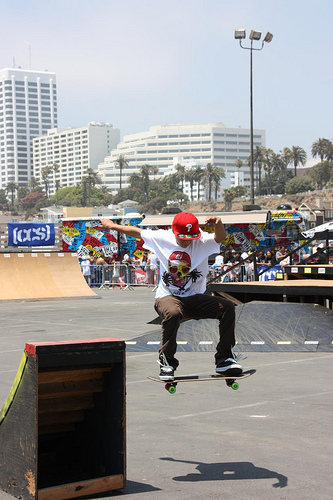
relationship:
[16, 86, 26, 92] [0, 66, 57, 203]
window of a building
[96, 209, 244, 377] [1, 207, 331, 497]
man in a park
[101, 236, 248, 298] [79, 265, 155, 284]
spectators standing near fence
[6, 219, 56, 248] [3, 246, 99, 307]
sign hung near ramp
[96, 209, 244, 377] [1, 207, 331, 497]
man in park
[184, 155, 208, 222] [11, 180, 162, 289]
palm trees in distance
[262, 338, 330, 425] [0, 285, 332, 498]
part of a surface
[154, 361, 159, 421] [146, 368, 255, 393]
part of a board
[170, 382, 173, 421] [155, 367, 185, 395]
part of a wheel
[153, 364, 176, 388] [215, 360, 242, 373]
part of a shoe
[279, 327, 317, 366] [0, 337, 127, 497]
part of a ramp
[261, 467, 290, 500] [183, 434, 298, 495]
part of a shadow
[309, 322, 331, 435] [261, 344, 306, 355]
edge of a court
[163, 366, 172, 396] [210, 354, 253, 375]
tip of a shoe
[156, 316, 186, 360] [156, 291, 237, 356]
part of a trousers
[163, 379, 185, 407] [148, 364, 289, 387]
wheel on skateboard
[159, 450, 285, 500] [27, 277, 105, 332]
shadow of pavement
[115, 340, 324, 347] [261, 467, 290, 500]
white dash on part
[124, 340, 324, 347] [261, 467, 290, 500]
white dash on part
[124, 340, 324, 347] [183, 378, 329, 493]
white dash on pavement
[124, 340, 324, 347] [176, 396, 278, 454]
white dash on pavement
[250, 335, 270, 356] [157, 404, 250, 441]
white dash on pavement